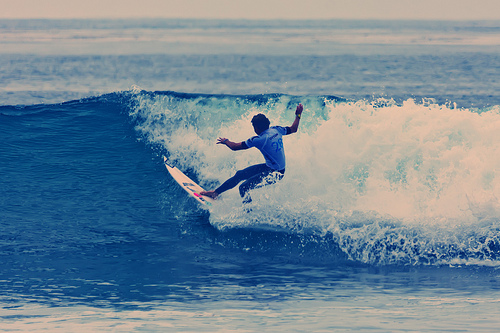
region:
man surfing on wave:
[87, 69, 347, 276]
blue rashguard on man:
[200, 100, 325, 210]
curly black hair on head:
[254, 120, 268, 130]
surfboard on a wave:
[142, 159, 218, 239]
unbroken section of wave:
[20, 73, 172, 293]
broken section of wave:
[180, 88, 450, 298]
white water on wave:
[336, 116, 454, 211]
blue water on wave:
[16, 67, 121, 299]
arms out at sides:
[193, 88, 319, 162]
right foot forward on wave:
[190, 165, 251, 212]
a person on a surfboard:
[117, 102, 328, 223]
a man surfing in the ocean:
[0, 80, 497, 275]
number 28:
[255, 130, 286, 157]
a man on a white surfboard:
[135, 92, 320, 247]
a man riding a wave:
[7, 75, 493, 282]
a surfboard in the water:
[6, 140, 476, 330]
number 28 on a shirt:
[225, 106, 295, 173]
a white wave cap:
[140, 90, 495, 257]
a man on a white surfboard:
[16, 75, 473, 286]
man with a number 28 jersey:
[110, 90, 321, 239]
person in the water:
[144, 85, 331, 229]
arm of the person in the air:
[286, 98, 313, 138]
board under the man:
[161, 161, 236, 223]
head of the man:
[249, 87, 286, 144]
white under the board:
[143, 150, 215, 202]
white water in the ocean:
[338, 123, 435, 196]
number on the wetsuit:
[264, 135, 289, 160]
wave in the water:
[18, 73, 206, 210]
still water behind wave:
[321, 43, 406, 91]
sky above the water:
[151, 5, 205, 40]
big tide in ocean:
[3, 90, 497, 253]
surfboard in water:
[156, 155, 227, 217]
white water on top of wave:
[180, 86, 499, 263]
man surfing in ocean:
[162, 100, 303, 225]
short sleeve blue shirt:
[235, 125, 302, 174]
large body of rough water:
[3, 17, 498, 329]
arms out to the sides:
[217, 100, 322, 152]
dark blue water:
[0, 99, 182, 302]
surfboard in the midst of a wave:
[0, 85, 495, 315]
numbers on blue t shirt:
[265, 130, 288, 170]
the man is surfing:
[88, 31, 433, 297]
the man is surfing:
[111, 85, 384, 236]